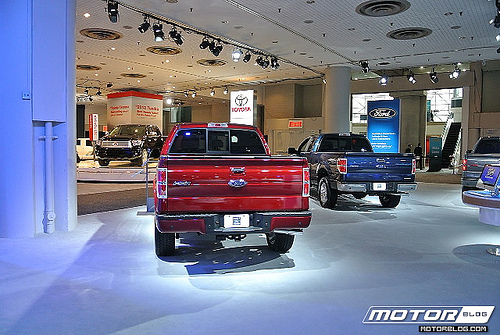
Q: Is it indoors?
A: Yes, it is indoors.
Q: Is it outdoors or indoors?
A: It is indoors.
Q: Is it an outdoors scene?
A: No, it is indoors.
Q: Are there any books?
A: No, there are no books.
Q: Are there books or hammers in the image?
A: No, there are no books or hammers.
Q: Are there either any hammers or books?
A: No, there are no books or hammers.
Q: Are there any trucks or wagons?
A: Yes, there is a truck.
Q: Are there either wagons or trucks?
A: Yes, there is a truck.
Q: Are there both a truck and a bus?
A: No, there is a truck but no buses.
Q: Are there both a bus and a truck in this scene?
A: No, there is a truck but no buses.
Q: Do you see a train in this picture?
A: No, there are no trains.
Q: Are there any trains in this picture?
A: No, there are no trains.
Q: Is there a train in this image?
A: No, there are no trains.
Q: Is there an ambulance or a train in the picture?
A: No, there are no trains or ambulances.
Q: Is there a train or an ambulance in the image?
A: No, there are no trains or ambulances.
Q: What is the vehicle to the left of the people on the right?
A: The vehicle is a truck.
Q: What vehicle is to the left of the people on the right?
A: The vehicle is a truck.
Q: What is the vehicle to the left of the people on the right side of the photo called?
A: The vehicle is a truck.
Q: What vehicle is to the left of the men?
A: The vehicle is a truck.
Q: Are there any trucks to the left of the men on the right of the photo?
A: Yes, there is a truck to the left of the men.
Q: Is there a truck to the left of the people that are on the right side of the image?
A: Yes, there is a truck to the left of the men.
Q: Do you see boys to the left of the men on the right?
A: No, there is a truck to the left of the men.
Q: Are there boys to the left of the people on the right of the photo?
A: No, there is a truck to the left of the men.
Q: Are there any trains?
A: No, there are no trains.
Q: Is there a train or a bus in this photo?
A: No, there are no trains or buses.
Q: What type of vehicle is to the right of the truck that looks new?
A: The vehicles are cars.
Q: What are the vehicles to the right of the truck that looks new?
A: The vehicles are cars.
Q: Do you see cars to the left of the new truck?
A: No, the cars are to the right of the truck.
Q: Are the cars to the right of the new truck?
A: Yes, the cars are to the right of the truck.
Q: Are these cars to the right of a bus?
A: No, the cars are to the right of the truck.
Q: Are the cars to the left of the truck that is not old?
A: No, the cars are to the right of the truck.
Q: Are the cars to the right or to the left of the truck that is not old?
A: The cars are to the right of the truck.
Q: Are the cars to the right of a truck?
A: Yes, the cars are to the right of a truck.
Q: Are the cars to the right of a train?
A: No, the cars are to the right of a truck.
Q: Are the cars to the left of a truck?
A: No, the cars are to the right of a truck.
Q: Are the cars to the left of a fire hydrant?
A: No, the cars are to the left of a truck.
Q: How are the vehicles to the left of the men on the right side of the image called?
A: The vehicles are cars.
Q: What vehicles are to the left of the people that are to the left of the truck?
A: The vehicles are cars.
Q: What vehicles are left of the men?
A: The vehicles are cars.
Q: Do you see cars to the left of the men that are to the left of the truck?
A: Yes, there are cars to the left of the men.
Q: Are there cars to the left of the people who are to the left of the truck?
A: Yes, there are cars to the left of the men.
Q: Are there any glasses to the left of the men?
A: No, there are cars to the left of the men.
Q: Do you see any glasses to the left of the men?
A: No, there are cars to the left of the men.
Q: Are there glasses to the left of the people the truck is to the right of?
A: No, there are cars to the left of the men.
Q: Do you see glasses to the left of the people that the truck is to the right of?
A: No, there are cars to the left of the men.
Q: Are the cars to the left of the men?
A: Yes, the cars are to the left of the men.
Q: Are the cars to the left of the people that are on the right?
A: Yes, the cars are to the left of the men.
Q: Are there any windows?
A: Yes, there is a window.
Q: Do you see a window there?
A: Yes, there is a window.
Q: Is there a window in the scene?
A: Yes, there is a window.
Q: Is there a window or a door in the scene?
A: Yes, there is a window.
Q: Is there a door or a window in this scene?
A: Yes, there is a window.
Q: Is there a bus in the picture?
A: No, there are no buses.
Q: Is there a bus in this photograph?
A: No, there are no buses.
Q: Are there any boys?
A: No, there are no boys.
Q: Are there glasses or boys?
A: No, there are no boys or glasses.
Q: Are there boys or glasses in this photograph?
A: No, there are no boys or glasses.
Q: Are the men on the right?
A: Yes, the men are on the right of the image.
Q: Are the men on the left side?
A: No, the men are on the right of the image.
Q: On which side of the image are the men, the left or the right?
A: The men are on the right of the image.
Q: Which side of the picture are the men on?
A: The men are on the right of the image.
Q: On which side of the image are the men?
A: The men are on the right of the image.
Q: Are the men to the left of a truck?
A: Yes, the men are to the left of a truck.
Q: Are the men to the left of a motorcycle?
A: No, the men are to the left of a truck.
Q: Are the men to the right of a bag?
A: No, the men are to the right of the truck.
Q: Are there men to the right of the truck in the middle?
A: Yes, there are men to the right of the truck.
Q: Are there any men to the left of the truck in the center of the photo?
A: No, the men are to the right of the truck.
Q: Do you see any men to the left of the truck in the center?
A: No, the men are to the right of the truck.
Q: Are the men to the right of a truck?
A: Yes, the men are to the right of a truck.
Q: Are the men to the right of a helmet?
A: No, the men are to the right of a truck.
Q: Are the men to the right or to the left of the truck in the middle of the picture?
A: The men are to the right of the truck.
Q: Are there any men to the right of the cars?
A: Yes, there are men to the right of the cars.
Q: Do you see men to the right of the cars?
A: Yes, there are men to the right of the cars.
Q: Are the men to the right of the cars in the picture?
A: Yes, the men are to the right of the cars.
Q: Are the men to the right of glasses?
A: No, the men are to the right of the cars.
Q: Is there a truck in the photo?
A: Yes, there is a truck.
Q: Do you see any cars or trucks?
A: Yes, there is a truck.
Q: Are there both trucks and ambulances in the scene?
A: No, there is a truck but no ambulances.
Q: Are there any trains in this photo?
A: No, there are no trains.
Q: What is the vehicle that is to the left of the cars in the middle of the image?
A: The vehicle is a truck.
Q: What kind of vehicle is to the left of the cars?
A: The vehicle is a truck.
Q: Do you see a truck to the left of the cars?
A: Yes, there is a truck to the left of the cars.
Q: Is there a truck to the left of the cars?
A: Yes, there is a truck to the left of the cars.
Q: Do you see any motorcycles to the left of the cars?
A: No, there is a truck to the left of the cars.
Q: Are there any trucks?
A: Yes, there is a truck.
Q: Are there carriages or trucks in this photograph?
A: Yes, there is a truck.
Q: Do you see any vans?
A: No, there are no vans.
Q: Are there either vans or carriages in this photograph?
A: No, there are no vans or carriages.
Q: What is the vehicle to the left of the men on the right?
A: The vehicle is a truck.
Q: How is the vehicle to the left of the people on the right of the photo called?
A: The vehicle is a truck.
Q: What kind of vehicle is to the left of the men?
A: The vehicle is a truck.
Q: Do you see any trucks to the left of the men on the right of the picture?
A: Yes, there is a truck to the left of the men.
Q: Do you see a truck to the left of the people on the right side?
A: Yes, there is a truck to the left of the men.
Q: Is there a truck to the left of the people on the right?
A: Yes, there is a truck to the left of the men.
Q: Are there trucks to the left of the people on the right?
A: Yes, there is a truck to the left of the men.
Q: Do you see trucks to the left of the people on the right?
A: Yes, there is a truck to the left of the men.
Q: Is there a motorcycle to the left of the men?
A: No, there is a truck to the left of the men.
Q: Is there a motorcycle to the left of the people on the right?
A: No, there is a truck to the left of the men.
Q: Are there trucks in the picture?
A: Yes, there is a truck.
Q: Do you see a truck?
A: Yes, there is a truck.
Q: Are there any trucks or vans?
A: Yes, there is a truck.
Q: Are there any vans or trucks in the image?
A: Yes, there is a truck.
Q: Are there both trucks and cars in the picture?
A: Yes, there are both a truck and a car.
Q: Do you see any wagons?
A: No, there are no wagons.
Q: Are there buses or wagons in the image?
A: No, there are no wagons or buses.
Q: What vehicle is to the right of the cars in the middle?
A: The vehicle is a truck.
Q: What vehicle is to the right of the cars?
A: The vehicle is a truck.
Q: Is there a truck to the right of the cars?
A: Yes, there is a truck to the right of the cars.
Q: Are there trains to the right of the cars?
A: No, there is a truck to the right of the cars.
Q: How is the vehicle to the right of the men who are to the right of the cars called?
A: The vehicle is a truck.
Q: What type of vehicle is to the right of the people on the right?
A: The vehicle is a truck.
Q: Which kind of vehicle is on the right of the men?
A: The vehicle is a truck.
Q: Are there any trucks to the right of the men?
A: Yes, there is a truck to the right of the men.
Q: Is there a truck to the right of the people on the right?
A: Yes, there is a truck to the right of the men.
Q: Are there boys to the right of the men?
A: No, there is a truck to the right of the men.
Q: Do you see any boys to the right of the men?
A: No, there is a truck to the right of the men.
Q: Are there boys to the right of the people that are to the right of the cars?
A: No, there is a truck to the right of the men.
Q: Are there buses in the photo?
A: No, there are no buses.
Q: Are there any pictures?
A: No, there are no pictures.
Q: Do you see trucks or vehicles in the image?
A: Yes, there is a truck.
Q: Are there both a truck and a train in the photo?
A: No, there is a truck but no trains.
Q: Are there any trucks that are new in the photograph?
A: Yes, there is a new truck.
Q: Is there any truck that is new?
A: Yes, there is a truck that is new.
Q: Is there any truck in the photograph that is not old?
A: Yes, there is an new truck.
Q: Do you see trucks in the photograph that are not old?
A: Yes, there is an new truck.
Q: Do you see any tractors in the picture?
A: No, there are no tractors.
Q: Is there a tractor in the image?
A: No, there are no tractors.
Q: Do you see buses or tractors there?
A: No, there are no tractors or buses.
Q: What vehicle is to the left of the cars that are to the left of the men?
A: The vehicle is a truck.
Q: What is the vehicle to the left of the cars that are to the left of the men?
A: The vehicle is a truck.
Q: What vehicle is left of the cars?
A: The vehicle is a truck.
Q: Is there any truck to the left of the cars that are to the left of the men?
A: Yes, there is a truck to the left of the cars.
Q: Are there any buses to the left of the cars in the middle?
A: No, there is a truck to the left of the cars.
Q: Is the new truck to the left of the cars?
A: Yes, the truck is to the left of the cars.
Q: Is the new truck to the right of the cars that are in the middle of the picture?
A: No, the truck is to the left of the cars.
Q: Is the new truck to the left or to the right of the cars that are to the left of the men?
A: The truck is to the left of the cars.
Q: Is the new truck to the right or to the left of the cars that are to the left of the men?
A: The truck is to the left of the cars.